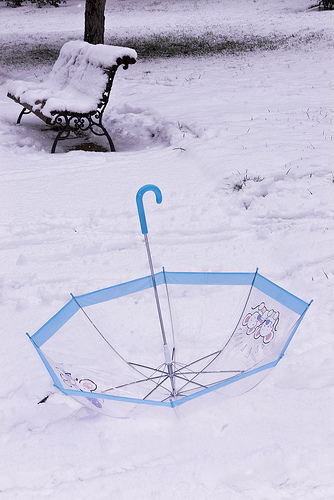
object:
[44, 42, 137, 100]
backrest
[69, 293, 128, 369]
wires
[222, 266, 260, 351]
wires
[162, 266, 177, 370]
wires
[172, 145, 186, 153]
grass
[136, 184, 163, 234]
handle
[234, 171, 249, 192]
dark grass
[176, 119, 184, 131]
dark grass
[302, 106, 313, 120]
dark grass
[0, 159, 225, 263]
snow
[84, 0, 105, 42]
tree trunk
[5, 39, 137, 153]
bench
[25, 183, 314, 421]
blue umbrella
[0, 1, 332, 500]
ground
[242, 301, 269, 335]
mouse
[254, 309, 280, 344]
mouse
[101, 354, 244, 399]
metal framework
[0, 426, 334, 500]
snow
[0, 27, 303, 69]
grass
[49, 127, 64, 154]
leg